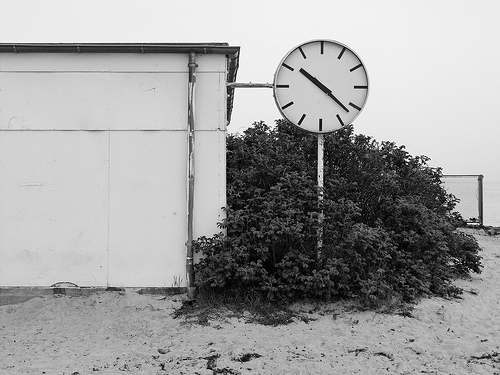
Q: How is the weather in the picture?
A: It is cloudy.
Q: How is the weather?
A: It is cloudy.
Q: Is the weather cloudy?
A: Yes, it is cloudy.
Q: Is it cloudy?
A: Yes, it is cloudy.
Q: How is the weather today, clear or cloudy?
A: It is cloudy.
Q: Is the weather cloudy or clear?
A: It is cloudy.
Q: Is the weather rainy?
A: No, it is cloudy.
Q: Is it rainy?
A: No, it is cloudy.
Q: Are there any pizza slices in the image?
A: No, there are no pizza slices.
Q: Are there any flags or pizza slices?
A: No, there are no pizza slices or flags.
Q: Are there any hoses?
A: No, there are no hoses.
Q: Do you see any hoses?
A: No, there are no hoses.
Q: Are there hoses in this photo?
A: No, there are no hoses.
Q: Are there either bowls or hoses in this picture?
A: No, there are no hoses or bowls.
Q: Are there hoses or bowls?
A: No, there are no hoses or bowls.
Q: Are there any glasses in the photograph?
A: No, there are no glasses.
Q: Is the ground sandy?
A: Yes, the ground is sandy.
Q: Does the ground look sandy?
A: Yes, the ground is sandy.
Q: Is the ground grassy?
A: No, the ground is sandy.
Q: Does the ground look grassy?
A: No, the ground is sandy.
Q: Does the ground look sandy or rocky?
A: The ground is sandy.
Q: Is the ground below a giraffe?
A: No, the ground is below the clock.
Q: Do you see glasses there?
A: No, there are no glasses.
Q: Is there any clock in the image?
A: Yes, there is a clock.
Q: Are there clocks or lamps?
A: Yes, there is a clock.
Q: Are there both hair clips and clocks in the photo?
A: No, there is a clock but no hair clips.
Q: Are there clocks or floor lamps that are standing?
A: Yes, the clock is standing.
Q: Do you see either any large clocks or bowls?
A: Yes, there is a large clock.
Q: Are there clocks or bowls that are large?
A: Yes, the clock is large.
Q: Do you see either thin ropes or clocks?
A: Yes, there is a thin clock.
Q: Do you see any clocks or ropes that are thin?
A: Yes, the clock is thin.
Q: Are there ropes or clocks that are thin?
A: Yes, the clock is thin.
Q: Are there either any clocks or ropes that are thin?
A: Yes, the clock is thin.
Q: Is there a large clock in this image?
A: Yes, there is a large clock.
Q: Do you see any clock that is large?
A: Yes, there is a clock that is large.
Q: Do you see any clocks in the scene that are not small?
A: Yes, there is a large clock.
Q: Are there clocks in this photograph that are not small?
A: Yes, there is a large clock.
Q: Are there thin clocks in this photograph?
A: Yes, there is a thin clock.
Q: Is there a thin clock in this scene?
A: Yes, there is a thin clock.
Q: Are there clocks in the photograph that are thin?
A: Yes, there is a clock that is thin.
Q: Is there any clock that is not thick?
A: Yes, there is a thin clock.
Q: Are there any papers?
A: No, there are no papers.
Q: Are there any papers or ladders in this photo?
A: No, there are no papers or ladders.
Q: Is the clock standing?
A: Yes, the clock is standing.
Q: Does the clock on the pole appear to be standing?
A: Yes, the clock is standing.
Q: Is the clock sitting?
A: No, the clock is standing.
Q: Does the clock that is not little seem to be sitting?
A: No, the clock is standing.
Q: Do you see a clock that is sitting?
A: No, there is a clock but it is standing.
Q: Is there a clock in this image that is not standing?
A: No, there is a clock but it is standing.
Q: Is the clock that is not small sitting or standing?
A: The clock is standing.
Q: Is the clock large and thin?
A: Yes, the clock is large and thin.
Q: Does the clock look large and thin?
A: Yes, the clock is large and thin.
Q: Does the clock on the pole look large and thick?
A: No, the clock is large but thin.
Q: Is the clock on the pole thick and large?
A: No, the clock is large but thin.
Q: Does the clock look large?
A: Yes, the clock is large.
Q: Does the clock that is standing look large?
A: Yes, the clock is large.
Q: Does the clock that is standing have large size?
A: Yes, the clock is large.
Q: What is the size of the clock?
A: The clock is large.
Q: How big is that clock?
A: The clock is large.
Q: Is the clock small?
A: No, the clock is large.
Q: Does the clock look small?
A: No, the clock is large.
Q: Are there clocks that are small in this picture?
A: No, there is a clock but it is large.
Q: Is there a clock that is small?
A: No, there is a clock but it is large.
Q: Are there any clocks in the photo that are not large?
A: No, there is a clock but it is large.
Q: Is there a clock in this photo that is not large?
A: No, there is a clock but it is large.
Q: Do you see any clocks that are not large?
A: No, there is a clock but it is large.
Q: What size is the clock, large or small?
A: The clock is large.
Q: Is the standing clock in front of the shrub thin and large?
A: Yes, the clock is thin and large.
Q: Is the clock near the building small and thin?
A: No, the clock is thin but large.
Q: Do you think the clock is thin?
A: Yes, the clock is thin.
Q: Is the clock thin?
A: Yes, the clock is thin.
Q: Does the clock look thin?
A: Yes, the clock is thin.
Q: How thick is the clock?
A: The clock is thin.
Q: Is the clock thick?
A: No, the clock is thin.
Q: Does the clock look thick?
A: No, the clock is thin.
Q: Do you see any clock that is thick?
A: No, there is a clock but it is thin.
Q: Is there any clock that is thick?
A: No, there is a clock but it is thin.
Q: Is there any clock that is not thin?
A: No, there is a clock but it is thin.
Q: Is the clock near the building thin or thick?
A: The clock is thin.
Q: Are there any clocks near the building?
A: Yes, there is a clock near the building.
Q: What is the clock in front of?
A: The clock is in front of the shrub.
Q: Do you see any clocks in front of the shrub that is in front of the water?
A: Yes, there is a clock in front of the bush.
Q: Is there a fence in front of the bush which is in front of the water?
A: No, there is a clock in front of the shrub.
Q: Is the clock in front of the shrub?
A: Yes, the clock is in front of the shrub.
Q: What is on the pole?
A: The clock is on the pole.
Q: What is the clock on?
A: The clock is on the pole.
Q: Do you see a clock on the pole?
A: Yes, there is a clock on the pole.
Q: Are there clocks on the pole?
A: Yes, there is a clock on the pole.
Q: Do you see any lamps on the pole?
A: No, there is a clock on the pole.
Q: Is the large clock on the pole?
A: Yes, the clock is on the pole.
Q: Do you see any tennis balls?
A: No, there are no tennis balls.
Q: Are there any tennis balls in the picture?
A: No, there are no tennis balls.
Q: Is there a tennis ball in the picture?
A: No, there are no tennis balls.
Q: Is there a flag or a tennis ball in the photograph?
A: No, there are no tennis balls or flags.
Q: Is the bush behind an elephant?
A: No, the bush is behind the clock.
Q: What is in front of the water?
A: The shrub is in front of the water.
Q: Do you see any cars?
A: No, there are no cars.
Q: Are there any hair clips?
A: No, there are no hair clips.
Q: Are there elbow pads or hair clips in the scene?
A: No, there are no hair clips or elbow pads.